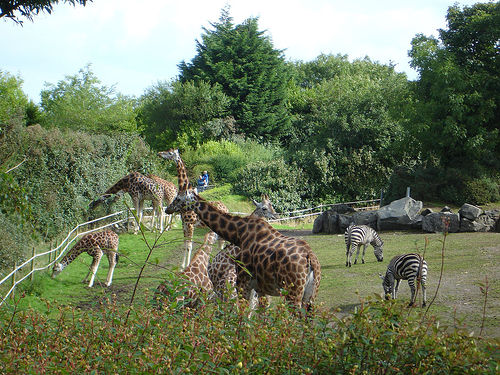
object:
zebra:
[382, 252, 430, 309]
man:
[195, 169, 210, 193]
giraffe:
[156, 148, 230, 265]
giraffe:
[164, 182, 323, 317]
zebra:
[341, 224, 386, 265]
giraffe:
[50, 228, 120, 288]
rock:
[376, 196, 423, 228]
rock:
[421, 211, 460, 234]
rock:
[457, 202, 483, 219]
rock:
[351, 208, 379, 226]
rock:
[313, 208, 344, 233]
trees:
[174, 2, 296, 182]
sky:
[0, 1, 500, 111]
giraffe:
[152, 229, 217, 313]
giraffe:
[91, 173, 181, 233]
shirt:
[197, 175, 207, 183]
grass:
[0, 267, 499, 373]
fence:
[0, 189, 388, 309]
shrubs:
[0, 126, 167, 276]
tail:
[313, 256, 323, 312]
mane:
[190, 190, 245, 219]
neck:
[192, 195, 246, 248]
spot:
[255, 230, 269, 241]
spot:
[240, 235, 254, 250]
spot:
[276, 250, 286, 262]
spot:
[237, 225, 246, 236]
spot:
[291, 253, 299, 263]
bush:
[277, 51, 424, 198]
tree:
[107, 200, 253, 326]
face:
[163, 186, 196, 215]